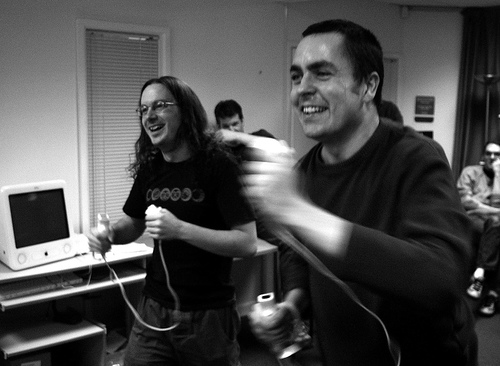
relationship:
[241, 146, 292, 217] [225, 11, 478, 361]
hand of man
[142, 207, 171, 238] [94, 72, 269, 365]
fist of man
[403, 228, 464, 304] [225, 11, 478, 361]
elbow of man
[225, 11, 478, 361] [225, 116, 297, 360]
man holding wii controllers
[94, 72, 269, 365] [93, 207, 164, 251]
man holding wii controllers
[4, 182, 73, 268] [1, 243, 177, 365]
computer on desk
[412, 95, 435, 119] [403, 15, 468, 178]
sign on wall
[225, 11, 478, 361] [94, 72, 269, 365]
man standing next to man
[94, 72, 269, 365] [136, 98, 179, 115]
man wearing glasses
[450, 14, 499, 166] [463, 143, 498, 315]
curtains behind man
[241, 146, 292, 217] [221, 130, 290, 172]
hand holding controller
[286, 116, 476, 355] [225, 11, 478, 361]
shirt of man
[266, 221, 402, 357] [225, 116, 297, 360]
cable connected to wii controllers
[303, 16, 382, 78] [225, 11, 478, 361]
hair of man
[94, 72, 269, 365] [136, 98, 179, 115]
man with glasses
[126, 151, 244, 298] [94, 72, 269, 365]
shirt of man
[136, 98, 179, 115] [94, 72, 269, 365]
glasses of man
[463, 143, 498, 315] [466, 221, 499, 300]
man sitting crossed legged